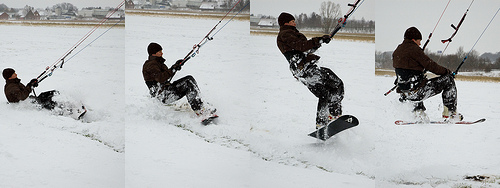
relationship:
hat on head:
[272, 12, 294, 23] [278, 12, 299, 28]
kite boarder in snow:
[385, 25, 483, 125] [0, 14, 497, 186]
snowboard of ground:
[301, 114, 367, 143] [251, 27, 374, 185]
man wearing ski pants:
[141, 43, 218, 126] [290, 64, 352, 119]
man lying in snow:
[2, 68, 85, 121] [16, 124, 307, 186]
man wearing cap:
[141, 43, 218, 126] [144, 43, 163, 53]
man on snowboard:
[272, 10, 343, 123] [303, 110, 363, 150]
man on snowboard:
[2, 66, 86, 121] [74, 98, 86, 119]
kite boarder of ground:
[382, 25, 485, 125] [377, 69, 499, 186]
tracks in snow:
[42, 112, 497, 186] [0, 14, 497, 186]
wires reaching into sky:
[163, 0, 248, 83] [121, 0, 248, 10]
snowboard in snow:
[393, 115, 485, 125] [0, 14, 497, 186]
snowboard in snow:
[301, 114, 367, 143] [0, 14, 497, 186]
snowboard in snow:
[200, 114, 219, 126] [0, 14, 497, 186]